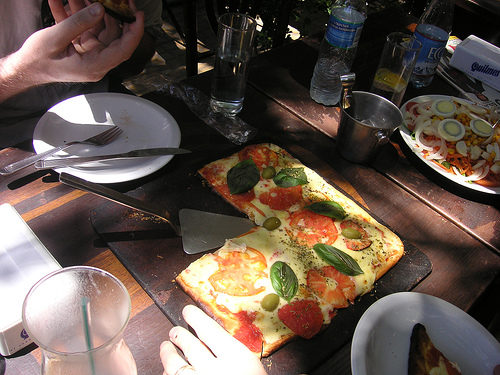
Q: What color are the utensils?
A: Silver.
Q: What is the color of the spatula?
A: Silver.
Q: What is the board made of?
A: Wood.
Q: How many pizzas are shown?
A: One.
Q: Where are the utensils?
A: On plate.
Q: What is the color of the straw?
A: Green.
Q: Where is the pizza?
A: On board.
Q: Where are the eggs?
A: On salad.